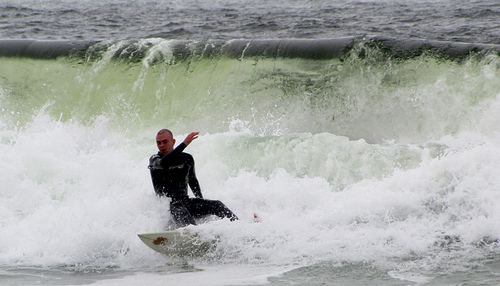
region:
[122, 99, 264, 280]
Surfer in black suit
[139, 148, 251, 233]
Black wet suit of surfer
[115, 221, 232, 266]
White surfboard with logo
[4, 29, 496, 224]
Wave the man in riding on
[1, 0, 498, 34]
Water behind wave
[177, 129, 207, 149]
Surfer's hand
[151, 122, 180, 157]
Bald head of surfer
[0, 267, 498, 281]
Water just in front of wave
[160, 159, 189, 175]
Logo on man's wet suit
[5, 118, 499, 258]
Crashing part of wave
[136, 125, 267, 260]
A man is surfing the waves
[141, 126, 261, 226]
The man is wearing a black wetsuit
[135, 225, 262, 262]
The surfboard is white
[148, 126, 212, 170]
The man's right arm is up in the air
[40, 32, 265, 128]
A tall wave is rolling in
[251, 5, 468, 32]
The ocean appears dark when there are no waves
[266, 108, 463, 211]
The water is white when waves crash down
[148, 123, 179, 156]
Man's hair is cut very short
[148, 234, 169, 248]
A red symbol is on the bottom of the surfboard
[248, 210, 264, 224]
Part of his left foot is sticking out of the water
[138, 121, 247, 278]
Man is in ocean.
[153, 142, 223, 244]
Man wearing wetsuit.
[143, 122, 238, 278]
Wet suit on man is black.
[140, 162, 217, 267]
Man is on surfboard.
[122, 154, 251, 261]
Surfboard is white in color.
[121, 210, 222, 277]
Front of surfboard is poking out of water.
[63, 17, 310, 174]
Large waves behind man.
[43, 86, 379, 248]
Waves are white in color on the tops.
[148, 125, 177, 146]
Man has short dark hair.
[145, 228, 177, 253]
Small logo on front of surfboard.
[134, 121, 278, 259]
Surfer is standing on surfboard.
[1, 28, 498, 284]
Water is white and foamy.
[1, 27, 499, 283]
Ocean waters appear chaotic.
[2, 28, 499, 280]
The water is turbulent.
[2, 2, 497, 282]
Water increasing in intensity.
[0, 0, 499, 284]
The ocean water is rugged.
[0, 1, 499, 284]
Boisterous waters meeting up with surfer.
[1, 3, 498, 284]
Ragine wave builds in ocean waters.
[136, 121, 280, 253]
Surfer has maintained control.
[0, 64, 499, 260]
White waters are rough.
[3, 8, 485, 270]
man surfing in the waves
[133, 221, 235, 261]
surf board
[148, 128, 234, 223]
man in a wet suit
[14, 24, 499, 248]
medium sized wave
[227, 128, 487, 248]
white ocean water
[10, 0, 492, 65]
dark colored ocean water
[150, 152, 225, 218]
black wet suit in the water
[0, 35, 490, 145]
one continious wave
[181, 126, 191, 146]
man's hand near the water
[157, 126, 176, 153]
man's closely shaven head